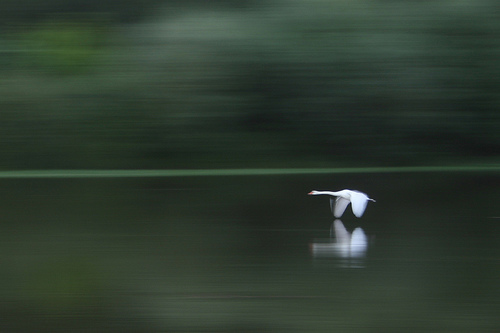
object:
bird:
[305, 188, 377, 219]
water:
[0, 2, 499, 333]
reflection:
[308, 218, 379, 269]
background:
[3, 8, 500, 89]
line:
[0, 164, 499, 180]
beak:
[306, 191, 314, 196]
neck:
[317, 190, 340, 198]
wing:
[348, 189, 370, 219]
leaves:
[15, 15, 113, 82]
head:
[306, 189, 320, 196]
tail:
[366, 196, 377, 203]